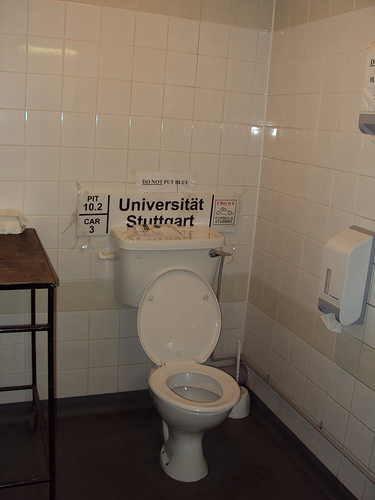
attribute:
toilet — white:
[121, 285, 268, 480]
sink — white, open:
[114, 216, 231, 256]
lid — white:
[136, 260, 223, 345]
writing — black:
[122, 192, 210, 230]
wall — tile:
[100, 38, 244, 144]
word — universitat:
[113, 190, 217, 212]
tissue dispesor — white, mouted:
[301, 244, 370, 332]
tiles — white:
[260, 79, 337, 146]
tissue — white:
[319, 315, 344, 333]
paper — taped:
[74, 174, 121, 215]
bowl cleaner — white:
[234, 380, 263, 424]